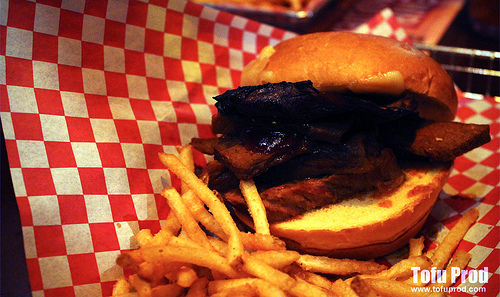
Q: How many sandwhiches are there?
A: One.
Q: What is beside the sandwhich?
A: French fries.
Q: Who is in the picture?
A: No one is in the picture.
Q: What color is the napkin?
A: Red and white.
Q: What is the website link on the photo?
A: www.tofuprod.com.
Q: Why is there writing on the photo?
A: An advertisement.